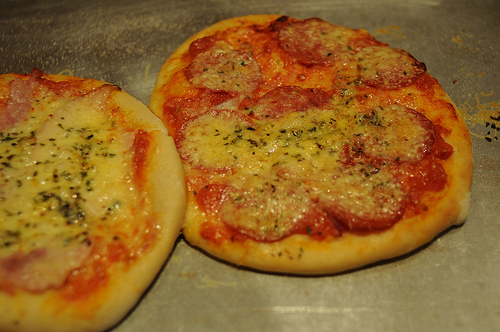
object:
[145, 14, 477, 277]
pizza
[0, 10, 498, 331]
table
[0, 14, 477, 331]
two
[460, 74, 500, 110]
crumbs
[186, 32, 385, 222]
pan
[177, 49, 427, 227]
cheese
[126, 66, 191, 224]
crust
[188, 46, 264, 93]
pepperoni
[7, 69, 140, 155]
ham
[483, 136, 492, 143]
black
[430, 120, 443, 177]
sauce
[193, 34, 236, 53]
tomatoes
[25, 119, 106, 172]
herbs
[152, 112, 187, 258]
dough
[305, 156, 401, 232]
canadian bacon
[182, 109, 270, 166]
cheese